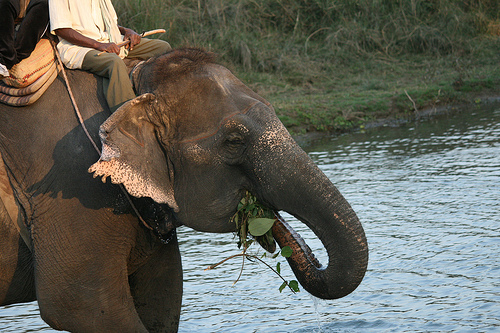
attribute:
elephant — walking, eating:
[0, 59, 387, 329]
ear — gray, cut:
[88, 87, 177, 206]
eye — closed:
[223, 130, 247, 150]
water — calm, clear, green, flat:
[0, 105, 496, 332]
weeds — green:
[238, 196, 313, 290]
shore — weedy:
[232, 8, 490, 135]